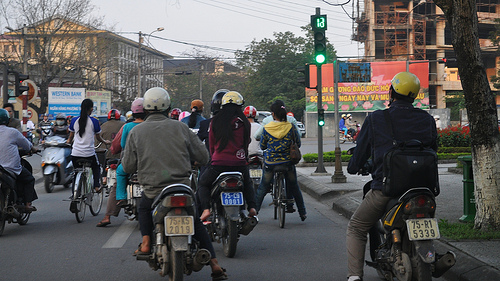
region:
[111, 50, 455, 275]
people riding motorcycles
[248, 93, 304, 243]
woman riding a bicycle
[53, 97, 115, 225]
woman with long black hair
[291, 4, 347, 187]
traffic light is green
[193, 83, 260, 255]
couple riding double on motorcycle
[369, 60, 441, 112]
man wearing yellow helmet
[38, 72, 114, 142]
sign advertising Western Bank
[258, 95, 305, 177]
woman wearing blue and yellow hoodie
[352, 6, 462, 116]
tall building under construction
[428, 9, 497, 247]
tree with white paint on trunk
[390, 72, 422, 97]
The yellow helmet on the guy wearing a black jacket.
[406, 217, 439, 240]
The license plate on the motorcycle with the guy in the yellow helmet.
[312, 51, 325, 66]
The green traffic light.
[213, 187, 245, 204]
The blue license plate on the motorcycle.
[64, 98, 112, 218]
The girl in the white and blue shirt on the bicycle.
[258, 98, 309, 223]
The girl in the yellow and blue hoody on the bicycle.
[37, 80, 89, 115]
The blue and white sign on the left.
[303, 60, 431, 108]
The pink and yellow sign on the right.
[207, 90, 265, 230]
The girl in the burgundy sweater with her back to the camera.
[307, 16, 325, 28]
The numbers above the green traffic light.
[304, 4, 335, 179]
Traffic light on corner of a street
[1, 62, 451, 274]
People driving bikes and motorcycles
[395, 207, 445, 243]
Plate of a motorcycle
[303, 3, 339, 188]
Traffic light is in green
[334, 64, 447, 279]
Motorcyclist has yellow helmet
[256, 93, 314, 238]
Woman riding a bike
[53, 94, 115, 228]
Woman riding a bike wears t-shirt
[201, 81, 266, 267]
Two persons riding in a motorcycle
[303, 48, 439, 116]
Advertisement board on corner of a street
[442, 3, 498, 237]
Trunk of a tree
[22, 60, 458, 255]
people on bikes at busy intersection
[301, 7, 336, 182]
traffic light illuminated green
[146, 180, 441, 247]
license plates on back of bikes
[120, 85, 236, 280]
biker with a foot on the street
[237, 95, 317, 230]
passenger with legs away from wheel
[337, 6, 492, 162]
construction of building on corner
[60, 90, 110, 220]
woman with long black hair riding bibycle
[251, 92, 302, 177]
yellow hood behind printed jacket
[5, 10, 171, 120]
large white and yellow building on other side of street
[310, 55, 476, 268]
biker with yellow helmet and black bag on back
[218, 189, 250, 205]
blue license plate on scooter.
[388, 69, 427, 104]
yellow helmet on person's head.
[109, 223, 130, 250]
white line painted on road.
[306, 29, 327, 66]
green traffic light.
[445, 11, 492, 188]
tree on side of road.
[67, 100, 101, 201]
person on a bicycle.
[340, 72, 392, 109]
writing on a billboard.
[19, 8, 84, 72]
bare branches on tree.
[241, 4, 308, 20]
telephone wires above street.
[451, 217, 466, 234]
grass on the sidewalk.